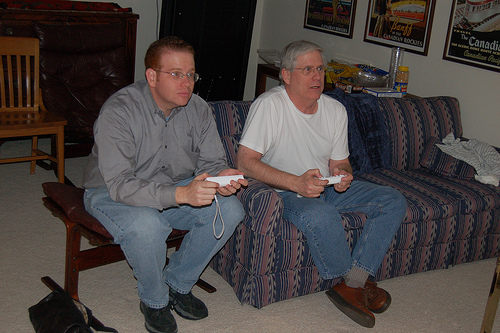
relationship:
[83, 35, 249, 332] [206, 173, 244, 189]
man holding controller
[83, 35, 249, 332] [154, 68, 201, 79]
man wears glasses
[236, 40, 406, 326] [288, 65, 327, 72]
man wears glasses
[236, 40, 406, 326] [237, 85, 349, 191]
man wears shirt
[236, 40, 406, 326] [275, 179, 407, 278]
man wears blue jeans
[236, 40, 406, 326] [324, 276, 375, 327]
man wears shoe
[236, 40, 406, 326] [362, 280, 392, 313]
man wears shoe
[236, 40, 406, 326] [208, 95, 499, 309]
man sits on sofa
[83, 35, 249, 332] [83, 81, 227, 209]
man wears shirt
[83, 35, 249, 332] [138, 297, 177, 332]
man wears shoe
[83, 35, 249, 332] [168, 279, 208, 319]
man wears shoe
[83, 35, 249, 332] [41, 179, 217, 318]
man sits on seat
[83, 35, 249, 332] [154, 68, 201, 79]
man with glasses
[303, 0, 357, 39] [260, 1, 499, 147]
framed poster on wall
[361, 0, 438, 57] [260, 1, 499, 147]
framed poster on wall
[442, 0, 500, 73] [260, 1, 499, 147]
framed poster on wall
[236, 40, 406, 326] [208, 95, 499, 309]
man on sofa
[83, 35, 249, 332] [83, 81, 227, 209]
man wearing shirt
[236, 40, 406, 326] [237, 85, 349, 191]
man wearing shirt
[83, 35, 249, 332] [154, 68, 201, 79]
man has glasses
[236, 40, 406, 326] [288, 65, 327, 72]
man has glasses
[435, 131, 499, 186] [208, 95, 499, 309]
shirt on sofa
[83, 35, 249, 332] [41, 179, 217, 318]
man on seat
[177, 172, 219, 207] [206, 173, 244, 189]
hand holding controller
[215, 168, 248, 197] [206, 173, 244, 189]
hand holding controller